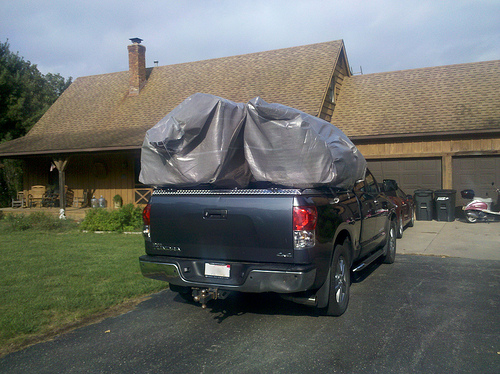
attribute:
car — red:
[386, 175, 425, 238]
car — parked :
[380, 177, 423, 249]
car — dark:
[373, 139, 429, 244]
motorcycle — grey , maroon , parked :
[455, 184, 495, 226]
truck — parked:
[140, 157, 402, 318]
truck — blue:
[146, 133, 434, 322]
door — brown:
[453, 154, 498, 217]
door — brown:
[368, 158, 442, 198]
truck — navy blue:
[136, 122, 407, 316]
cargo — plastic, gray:
[111, 81, 364, 208]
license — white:
[205, 262, 232, 277]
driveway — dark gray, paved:
[377, 228, 499, 354]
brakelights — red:
[291, 204, 318, 249]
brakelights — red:
[141, 200, 151, 242]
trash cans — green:
[417, 186, 457, 232]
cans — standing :
[431, 184, 456, 224]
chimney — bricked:
[126, 35, 148, 90]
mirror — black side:
[373, 170, 408, 195]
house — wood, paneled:
[3, 35, 498, 230]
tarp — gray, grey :
[135, 92, 372, 189]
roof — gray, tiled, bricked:
[0, 39, 352, 153]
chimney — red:
[128, 37, 145, 92]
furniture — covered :
[131, 86, 372, 195]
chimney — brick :
[123, 32, 148, 85]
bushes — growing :
[77, 200, 139, 230]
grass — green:
[14, 229, 124, 304]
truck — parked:
[140, 91, 399, 318]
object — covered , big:
[139, 91, 365, 191]